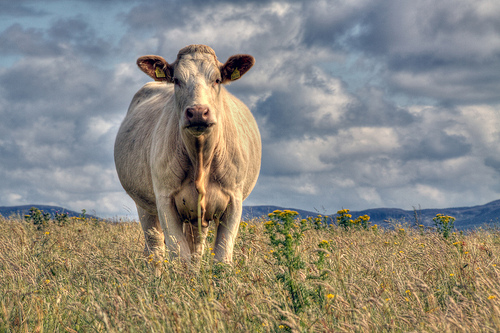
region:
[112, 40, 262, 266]
A cow in a field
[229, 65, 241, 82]
yellow tag in the cow's ear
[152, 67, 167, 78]
yellow tag in the cow's ear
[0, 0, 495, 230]
A grey cloudy sky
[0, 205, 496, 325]
A grassy field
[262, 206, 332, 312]
A tall yellow flower in the field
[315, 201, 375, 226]
A group of yellow flowers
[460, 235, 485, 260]
some red flowers in the field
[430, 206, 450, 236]
A tall yellow flower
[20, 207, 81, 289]
some flowers in the fiels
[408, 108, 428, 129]
part of a cloud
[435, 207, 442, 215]
part of a hill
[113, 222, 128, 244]
part of a plantation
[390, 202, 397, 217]
part of a slope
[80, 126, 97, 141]
part of the sky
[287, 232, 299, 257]
part of a twig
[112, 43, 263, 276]
large tan cow standing in pasture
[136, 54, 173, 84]
large dark ear of cow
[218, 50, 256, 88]
large dark ear of cow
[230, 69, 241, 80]
yellow tag in ear of cow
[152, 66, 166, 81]
yellow tag in ear of cow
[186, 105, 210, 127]
large pink nose of cow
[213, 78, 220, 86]
small black eye of cow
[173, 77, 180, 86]
small black eye of cow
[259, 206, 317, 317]
large green and yellow plant near cow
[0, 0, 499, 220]
gloomy cloudy blue sky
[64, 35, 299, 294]
a large white cow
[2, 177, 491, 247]
mountains in the distance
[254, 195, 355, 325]
tall weeds with yellow tops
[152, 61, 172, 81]
yellow tag in left ear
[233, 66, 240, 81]
yellow tag in right ear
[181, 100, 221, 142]
brown nose of cow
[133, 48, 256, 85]
brown inside the ears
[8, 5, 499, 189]
white clouds in the sky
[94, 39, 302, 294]
a cow standing in tall grass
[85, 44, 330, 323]
a white cow standing in grass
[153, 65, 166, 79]
cow tagged on the ear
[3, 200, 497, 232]
blue mountains on the horizon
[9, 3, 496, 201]
mostly cloudy skies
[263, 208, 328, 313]
wildflowers growing in the field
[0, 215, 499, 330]
dry brush in the field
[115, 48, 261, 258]
large white cow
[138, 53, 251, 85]
both ears are tagged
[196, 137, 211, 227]
loose skin on the cows neck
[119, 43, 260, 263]
cow facing straight ahead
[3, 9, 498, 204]
large fluffy white clouds